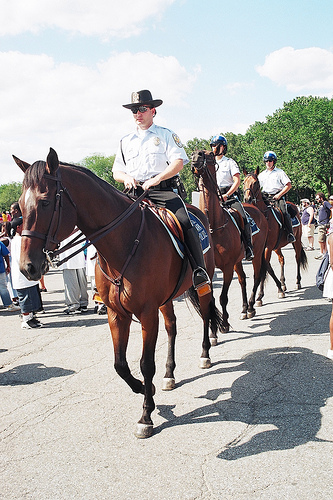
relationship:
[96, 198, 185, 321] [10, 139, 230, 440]
strap on horse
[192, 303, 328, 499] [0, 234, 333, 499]
cracked line on ground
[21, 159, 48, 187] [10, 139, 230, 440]
hair on horse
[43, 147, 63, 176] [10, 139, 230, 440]
ear on horse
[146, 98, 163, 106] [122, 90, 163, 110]
brim on hat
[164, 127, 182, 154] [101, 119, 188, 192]
lapel on shirt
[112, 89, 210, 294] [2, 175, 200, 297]
officer riding horse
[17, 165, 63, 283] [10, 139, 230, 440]
face on horse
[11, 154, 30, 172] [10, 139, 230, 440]
ear on horse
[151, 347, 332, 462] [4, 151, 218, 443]
horse's shadow of horse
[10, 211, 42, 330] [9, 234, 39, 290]
child in t-shirt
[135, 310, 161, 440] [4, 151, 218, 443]
leg of horse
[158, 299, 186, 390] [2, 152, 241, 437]
back legs of horse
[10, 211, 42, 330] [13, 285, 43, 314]
child wearing shorts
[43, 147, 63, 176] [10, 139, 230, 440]
ear of horse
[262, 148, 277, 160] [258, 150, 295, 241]
helmet of officer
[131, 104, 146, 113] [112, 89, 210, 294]
sunglasses of officer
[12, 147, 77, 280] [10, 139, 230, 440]
head of horse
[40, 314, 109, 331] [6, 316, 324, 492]
shadow on ground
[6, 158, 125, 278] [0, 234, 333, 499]
horse walking on ground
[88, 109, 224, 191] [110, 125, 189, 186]
shirt of officer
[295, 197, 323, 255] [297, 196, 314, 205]
man wearing cap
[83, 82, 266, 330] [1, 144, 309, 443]
cops riding horses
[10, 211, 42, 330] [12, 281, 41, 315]
child wearing shorts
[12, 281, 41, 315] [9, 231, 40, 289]
shorts wearing t-shirt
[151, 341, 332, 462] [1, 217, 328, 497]
horse's shadow on ground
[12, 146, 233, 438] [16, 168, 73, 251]
horse wearing bridle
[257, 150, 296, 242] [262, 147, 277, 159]
officer wearing helmet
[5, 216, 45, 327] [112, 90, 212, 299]
child watching officer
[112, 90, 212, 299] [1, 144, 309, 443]
officer riding horses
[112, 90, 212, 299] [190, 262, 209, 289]
officer feet in stirrups